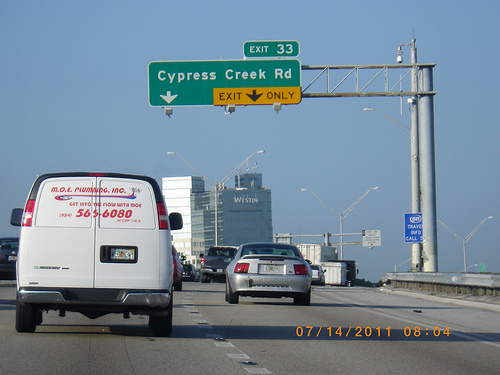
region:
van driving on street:
[6, 157, 197, 350]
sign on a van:
[42, 181, 147, 232]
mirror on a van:
[160, 205, 191, 235]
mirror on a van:
[0, 200, 30, 222]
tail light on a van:
[150, 190, 170, 240]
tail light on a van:
[15, 198, 45, 228]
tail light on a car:
[226, 258, 267, 273]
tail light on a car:
[286, 255, 309, 285]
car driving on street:
[222, 225, 318, 311]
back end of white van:
[7, 166, 187, 333]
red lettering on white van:
[43, 184, 148, 235]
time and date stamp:
[292, 321, 459, 352]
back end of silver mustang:
[218, 238, 313, 313]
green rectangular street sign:
[144, 53, 307, 116]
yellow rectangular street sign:
[207, 85, 302, 109]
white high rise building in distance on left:
[157, 171, 207, 263]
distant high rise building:
[206, 166, 280, 251]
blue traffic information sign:
[400, 208, 423, 248]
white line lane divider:
[172, 275, 265, 373]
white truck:
[32, 167, 165, 330]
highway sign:
[161, 48, 302, 127]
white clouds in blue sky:
[14, 3, 82, 66]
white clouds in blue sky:
[72, 22, 130, 95]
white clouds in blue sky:
[13, 52, 105, 85]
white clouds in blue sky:
[35, 76, 117, 106]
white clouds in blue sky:
[29, 119, 144, 158]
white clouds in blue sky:
[313, 111, 397, 160]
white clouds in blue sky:
[297, 146, 343, 171]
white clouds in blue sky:
[289, 146, 377, 211]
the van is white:
[0, 152, 194, 347]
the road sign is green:
[140, 52, 312, 120]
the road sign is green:
[108, 22, 323, 137]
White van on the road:
[11, 173, 181, 337]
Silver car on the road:
[226, 240, 314, 306]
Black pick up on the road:
[203, 245, 238, 285]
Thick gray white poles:
[408, 72, 439, 281]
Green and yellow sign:
[148, 60, 298, 105]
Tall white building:
[161, 174, 275, 254]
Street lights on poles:
[303, 180, 379, 262]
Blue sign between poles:
[406, 213, 423, 245]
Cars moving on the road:
[0, 163, 335, 327]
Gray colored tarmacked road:
[0, 284, 499, 374]